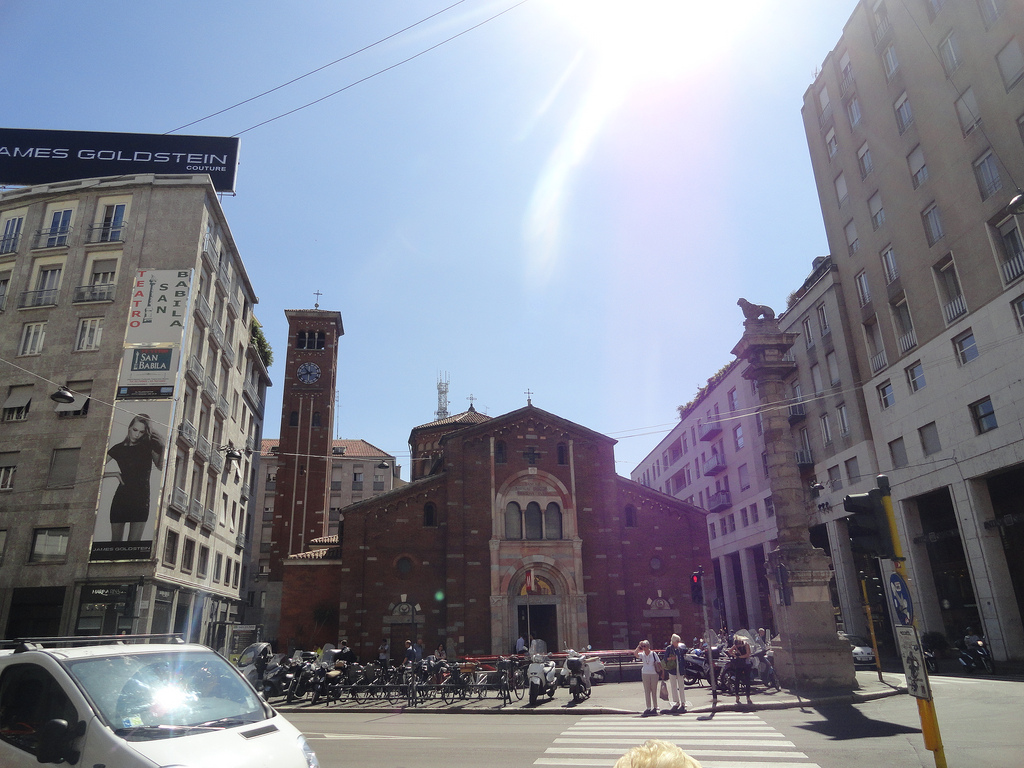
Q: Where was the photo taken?
A: On the street.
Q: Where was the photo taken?
A: On a city street.